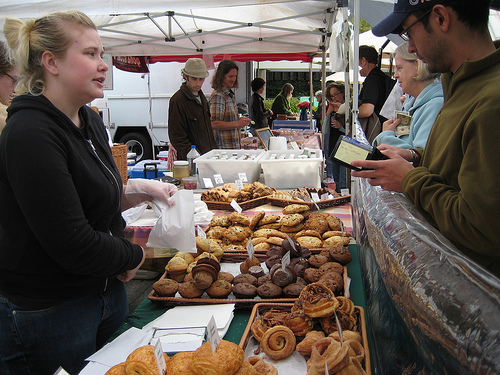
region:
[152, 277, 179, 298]
Baked muffin on a tray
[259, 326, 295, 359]
A baked donut next to others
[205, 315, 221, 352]
A white posted sign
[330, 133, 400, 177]
Wallet being opened by a man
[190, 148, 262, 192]
Container of some goods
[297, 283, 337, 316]
A delicious donut for sale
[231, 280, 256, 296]
A chocolate muffin in a tray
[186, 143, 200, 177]
A bottle of a drink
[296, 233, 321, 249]
A cookie in a tray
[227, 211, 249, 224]
Freshly baked cookie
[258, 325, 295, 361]
Tasty pastry in a container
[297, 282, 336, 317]
Baked donut with frosting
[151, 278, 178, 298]
A muffin next to others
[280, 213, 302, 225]
Chocolate chip cookie stacked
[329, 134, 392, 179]
A man's wallet opened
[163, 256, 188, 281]
Muffin freshly baked and ready for sale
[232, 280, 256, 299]
Chocolate muffin next to other muffins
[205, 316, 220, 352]
White sign posted for pastries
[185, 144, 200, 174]
A bottle of liquid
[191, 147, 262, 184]
Container full of goods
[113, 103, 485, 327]
view is at a chf counter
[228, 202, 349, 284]
snacks are brown in color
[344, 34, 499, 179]
man is opening the wallet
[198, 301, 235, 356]
the price tags are white in color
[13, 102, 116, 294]
jacket is black in color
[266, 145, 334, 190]
tray is white in color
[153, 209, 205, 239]
wrapped in a white polythene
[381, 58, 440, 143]
lady holdimg some money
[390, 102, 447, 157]
the seater is dull blue in color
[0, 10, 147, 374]
human is selling food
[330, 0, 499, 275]
human is buying food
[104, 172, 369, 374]
food is being sold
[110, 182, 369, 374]
pastries are being sold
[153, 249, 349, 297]
muffins are available for purchase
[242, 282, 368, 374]
pastries are available for purchase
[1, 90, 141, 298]
hooded sweatshirt is worn by woman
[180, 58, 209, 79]
hat is worn by man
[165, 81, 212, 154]
jacket is worn by man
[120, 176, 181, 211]
glove is worn by woman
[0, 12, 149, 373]
a woman serving baked goods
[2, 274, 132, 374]
jeans on a woman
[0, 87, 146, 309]
a black jacket on a woman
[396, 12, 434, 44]
glasses on a man's face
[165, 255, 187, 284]
a light brown muffin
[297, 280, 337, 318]
a nut crusted sweet rll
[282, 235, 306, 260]
a dark brown muffin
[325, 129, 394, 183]
a wallet in a man's hands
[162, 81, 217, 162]
a brown jacket on a man